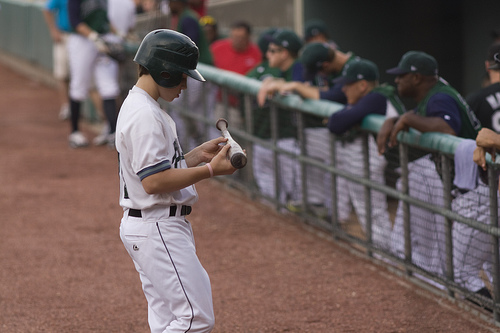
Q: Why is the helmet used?
A: Safety.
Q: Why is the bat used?
A: Play.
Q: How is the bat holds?
A: Hands.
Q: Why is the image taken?
A: Remembrance.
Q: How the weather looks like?
A: Good.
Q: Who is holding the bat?
A: A batter.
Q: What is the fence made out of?
A: Metal.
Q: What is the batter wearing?
A: A uniform.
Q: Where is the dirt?
A: On the ground.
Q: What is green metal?
A: The fence railing.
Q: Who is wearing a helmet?
A: The batter.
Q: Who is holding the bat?
A: The batter.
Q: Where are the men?
A: Leaning on the fence.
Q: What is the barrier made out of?
A: Metal.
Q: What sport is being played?
A: Baseball.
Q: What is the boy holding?
A: Baseball bat.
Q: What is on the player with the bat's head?
A: Helmet.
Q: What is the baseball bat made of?
A: Wood.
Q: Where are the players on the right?
A: Dugout.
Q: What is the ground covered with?
A: Gravel.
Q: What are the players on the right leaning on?
A: Rail.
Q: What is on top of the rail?
A: Protective padding.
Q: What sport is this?
A: Baseball.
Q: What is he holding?
A: Bat.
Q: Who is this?
A: Player.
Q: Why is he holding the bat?
A: To play.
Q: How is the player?
A: Standing.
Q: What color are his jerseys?
A: White.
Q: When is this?
A: Daytime.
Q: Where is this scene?
A: On a baseball field.